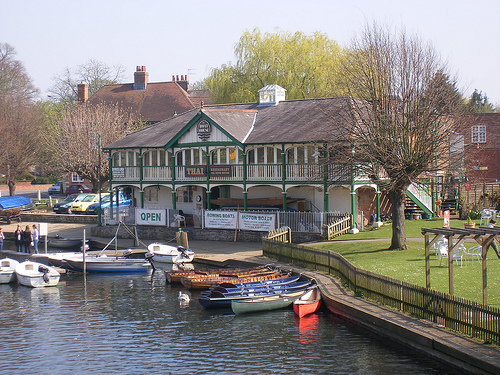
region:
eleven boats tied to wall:
[2, 242, 334, 334]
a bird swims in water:
[162, 279, 202, 313]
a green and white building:
[103, 80, 449, 255]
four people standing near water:
[0, 217, 47, 258]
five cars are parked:
[37, 170, 136, 221]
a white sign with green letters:
[126, 200, 179, 235]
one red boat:
[289, 280, 329, 331]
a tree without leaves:
[310, 8, 490, 270]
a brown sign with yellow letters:
[184, 162, 208, 181]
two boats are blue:
[187, 270, 320, 314]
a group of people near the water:
[0, 230, 48, 250]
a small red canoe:
[291, 287, 320, 318]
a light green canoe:
[230, 291, 291, 313]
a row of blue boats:
[197, 277, 298, 292]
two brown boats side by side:
[176, 270, 281, 283]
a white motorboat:
[152, 242, 194, 262]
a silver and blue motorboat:
[70, 260, 150, 272]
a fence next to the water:
[262, 231, 497, 330]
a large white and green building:
[133, 127, 366, 217]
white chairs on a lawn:
[421, 231, 485, 268]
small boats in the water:
[27, 204, 311, 374]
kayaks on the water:
[183, 232, 353, 363]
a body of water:
[59, 292, 216, 373]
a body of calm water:
[60, 295, 222, 368]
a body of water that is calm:
[87, 310, 207, 372]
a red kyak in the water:
[269, 270, 346, 340]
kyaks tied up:
[193, 239, 386, 359]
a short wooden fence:
[264, 187, 499, 337]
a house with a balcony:
[79, 38, 486, 291]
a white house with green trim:
[79, 77, 475, 269]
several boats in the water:
[166, 252, 313, 335]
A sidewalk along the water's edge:
[301, 254, 451, 373]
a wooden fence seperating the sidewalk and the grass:
[363, 263, 463, 328]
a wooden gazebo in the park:
[410, 217, 498, 290]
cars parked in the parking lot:
[37, 185, 124, 217]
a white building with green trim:
[99, 98, 371, 238]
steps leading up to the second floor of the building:
[382, 164, 447, 225]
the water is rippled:
[76, 301, 191, 366]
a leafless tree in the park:
[345, 89, 441, 259]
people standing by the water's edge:
[0, 216, 54, 256]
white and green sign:
[129, 203, 178, 230]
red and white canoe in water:
[291, 280, 337, 331]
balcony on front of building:
[92, 134, 357, 190]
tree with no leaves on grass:
[345, 69, 442, 268]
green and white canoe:
[221, 293, 311, 313]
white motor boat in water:
[13, 253, 80, 298]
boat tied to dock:
[139, 224, 228, 279]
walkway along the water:
[315, 264, 477, 373]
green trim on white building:
[116, 137, 362, 187]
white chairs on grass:
[425, 234, 495, 276]